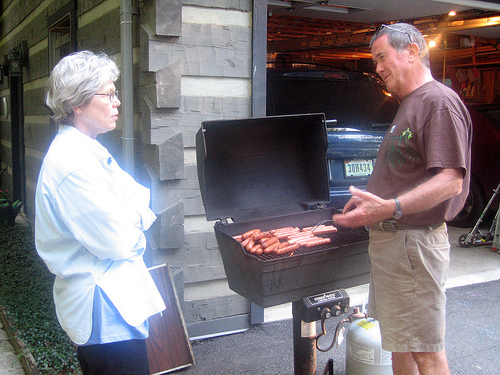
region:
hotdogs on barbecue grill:
[177, 105, 377, 371]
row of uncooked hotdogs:
[286, 229, 331, 246]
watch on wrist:
[384, 192, 406, 224]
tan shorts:
[356, 210, 462, 362]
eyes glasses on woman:
[85, 83, 125, 103]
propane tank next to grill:
[339, 303, 401, 373]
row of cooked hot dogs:
[240, 228, 301, 260]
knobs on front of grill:
[315, 303, 351, 324]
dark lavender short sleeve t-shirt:
[358, 73, 475, 237]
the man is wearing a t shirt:
[373, 80, 470, 225]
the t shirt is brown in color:
[365, 79, 473, 226]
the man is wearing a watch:
[392, 196, 404, 222]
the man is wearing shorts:
[365, 222, 457, 355]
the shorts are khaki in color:
[364, 225, 454, 358]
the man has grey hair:
[372, 18, 433, 62]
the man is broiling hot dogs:
[235, 217, 340, 252]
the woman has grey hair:
[41, 51, 116, 123]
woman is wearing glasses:
[85, 86, 120, 98]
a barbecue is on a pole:
[197, 111, 387, 373]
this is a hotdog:
[301, 235, 336, 250]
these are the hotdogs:
[229, 198, 344, 284]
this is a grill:
[182, 83, 413, 373]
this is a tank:
[336, 298, 398, 373]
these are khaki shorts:
[356, 190, 476, 365]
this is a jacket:
[25, 117, 187, 362]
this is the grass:
[11, 263, 33, 314]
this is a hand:
[325, 169, 407, 237]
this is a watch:
[383, 188, 417, 228]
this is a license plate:
[342, 135, 387, 195]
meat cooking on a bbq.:
[221, 217, 343, 266]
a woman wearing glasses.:
[32, 35, 122, 140]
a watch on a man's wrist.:
[386, 189, 406, 225]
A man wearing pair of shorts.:
[364, 218, 449, 358]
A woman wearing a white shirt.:
[26, 124, 170, 345]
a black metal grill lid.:
[188, 114, 336, 212]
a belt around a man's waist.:
[362, 216, 455, 234]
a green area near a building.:
[1, 216, 98, 373]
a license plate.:
[343, 152, 381, 184]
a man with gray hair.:
[368, 31, 438, 92]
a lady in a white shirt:
[50, 50, 176, 372]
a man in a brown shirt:
[360, 21, 432, 371]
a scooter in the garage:
[461, 195, 496, 250]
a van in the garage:
[290, 55, 380, 200]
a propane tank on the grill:
[335, 311, 390, 366]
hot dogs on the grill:
[242, 215, 327, 265]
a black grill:
[185, 110, 385, 360]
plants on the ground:
[5, 240, 57, 345]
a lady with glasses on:
[55, 60, 141, 200]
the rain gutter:
[120, 5, 135, 173]